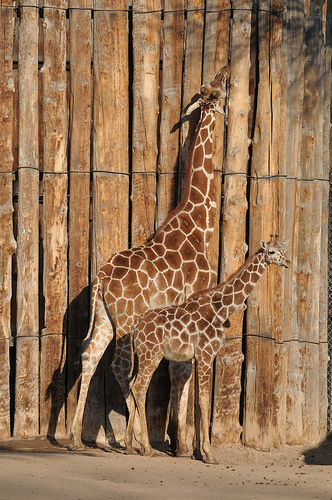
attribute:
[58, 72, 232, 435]
giraffe — larger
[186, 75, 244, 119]
giraffe's head — adult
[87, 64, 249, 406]
giraffe — adult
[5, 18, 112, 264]
fence — tall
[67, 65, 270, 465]
giraffes — captivity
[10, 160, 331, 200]
seam fence — wooden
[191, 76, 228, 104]
horns — dark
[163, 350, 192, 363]
belly — full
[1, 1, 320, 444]
wall — wood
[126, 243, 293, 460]
hair — black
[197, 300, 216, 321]
spots — brown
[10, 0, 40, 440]
log — wood